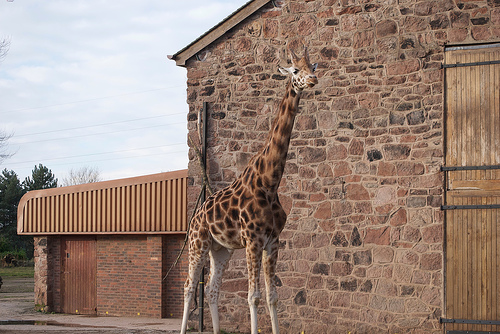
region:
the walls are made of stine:
[370, 110, 428, 311]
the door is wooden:
[450, 60, 488, 320]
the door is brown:
[445, 54, 495, 329]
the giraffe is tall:
[177, 67, 336, 325]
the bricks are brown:
[97, 240, 189, 332]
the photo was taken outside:
[5, 43, 497, 332]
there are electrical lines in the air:
[48, 106, 177, 168]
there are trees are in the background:
[6, 168, 68, 186]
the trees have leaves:
[3, 165, 58, 185]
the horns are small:
[263, 47, 328, 94]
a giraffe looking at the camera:
[163, 35, 308, 331]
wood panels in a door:
[453, 228, 490, 310]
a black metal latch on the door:
[441, 316, 486, 329]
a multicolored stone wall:
[340, 57, 429, 309]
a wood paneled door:
[63, 242, 91, 317]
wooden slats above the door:
[27, 197, 170, 229]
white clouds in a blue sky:
[59, 105, 108, 145]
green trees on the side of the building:
[2, 172, 22, 250]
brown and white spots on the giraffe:
[220, 187, 269, 226]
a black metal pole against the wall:
[189, 97, 217, 162]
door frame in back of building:
[62, 241, 98, 311]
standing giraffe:
[279, 49, 316, 227]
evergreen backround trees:
[2, 169, 36, 281]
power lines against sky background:
[2, 95, 183, 170]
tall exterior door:
[444, 48, 499, 305]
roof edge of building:
[164, 0, 281, 55]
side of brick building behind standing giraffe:
[324, 92, 427, 321]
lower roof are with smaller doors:
[17, 196, 191, 230]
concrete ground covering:
[7, 303, 122, 333]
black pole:
[194, 100, 214, 205]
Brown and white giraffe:
[183, 49, 321, 330]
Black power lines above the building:
[11, 107, 192, 172]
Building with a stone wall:
[178, 8, 487, 326]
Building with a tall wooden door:
[411, 27, 492, 327]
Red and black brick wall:
[84, 235, 184, 316]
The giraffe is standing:
[178, 40, 320, 330]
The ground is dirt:
[6, 283, 81, 320]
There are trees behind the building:
[10, 157, 101, 272]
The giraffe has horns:
[276, 37, 318, 68]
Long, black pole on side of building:
[184, 95, 218, 325]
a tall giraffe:
[153, 45, 332, 332]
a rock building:
[316, 18, 433, 332]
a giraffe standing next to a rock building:
[138, 20, 450, 331]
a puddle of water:
[6, 307, 94, 332]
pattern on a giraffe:
[192, 184, 252, 239]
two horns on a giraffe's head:
[281, 40, 322, 108]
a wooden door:
[402, 187, 489, 332]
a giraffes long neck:
[238, 38, 333, 213]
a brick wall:
[102, 244, 159, 314]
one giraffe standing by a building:
[123, 40, 345, 321]